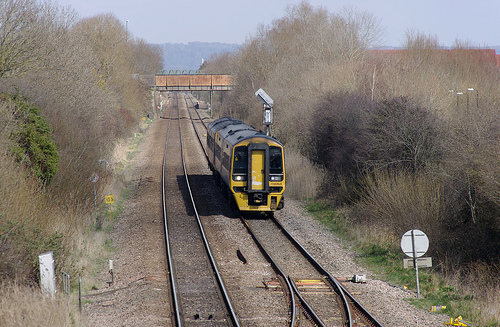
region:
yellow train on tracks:
[202, 112, 285, 220]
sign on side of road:
[100, 190, 124, 207]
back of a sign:
[400, 222, 430, 294]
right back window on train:
[269, 153, 280, 173]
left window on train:
[233, 142, 247, 179]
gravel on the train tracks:
[206, 223, 246, 247]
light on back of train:
[233, 174, 242, 183]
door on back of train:
[252, 145, 262, 191]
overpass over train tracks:
[137, 69, 245, 89]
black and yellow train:
[190, 103, 295, 228]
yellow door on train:
[242, 131, 262, 198]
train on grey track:
[245, 194, 346, 324]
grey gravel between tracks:
[179, 219, 346, 304]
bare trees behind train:
[229, 0, 427, 196]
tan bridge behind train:
[142, 69, 229, 95]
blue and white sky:
[144, 6, 241, 45]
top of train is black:
[205, 107, 265, 156]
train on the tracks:
[191, 102, 291, 218]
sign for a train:
[382, 214, 455, 316]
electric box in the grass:
[29, 240, 73, 322]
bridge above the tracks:
[152, 62, 239, 99]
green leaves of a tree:
[17, 108, 70, 193]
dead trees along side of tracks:
[295, 44, 456, 194]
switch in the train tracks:
[271, 280, 364, 319]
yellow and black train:
[205, 86, 285, 208]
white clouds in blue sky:
[135, 2, 187, 26]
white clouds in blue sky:
[207, 12, 238, 49]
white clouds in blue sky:
[237, 19, 288, 44]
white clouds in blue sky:
[371, 8, 408, 45]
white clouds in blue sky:
[8, 11, 48, 35]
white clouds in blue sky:
[48, 2, 115, 50]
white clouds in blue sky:
[110, 9, 171, 47]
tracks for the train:
[137, 208, 399, 320]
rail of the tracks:
[145, 108, 188, 323]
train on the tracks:
[189, 70, 298, 257]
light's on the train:
[215, 173, 289, 190]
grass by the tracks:
[283, 206, 409, 283]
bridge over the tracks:
[136, 64, 240, 114]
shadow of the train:
[166, 158, 210, 226]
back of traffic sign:
[393, 225, 438, 300]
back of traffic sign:
[397, 217, 440, 305]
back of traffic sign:
[379, 215, 452, 300]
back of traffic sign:
[389, 217, 441, 304]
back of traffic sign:
[384, 217, 446, 299]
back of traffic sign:
[380, 212, 445, 299]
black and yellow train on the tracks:
[204, 116, 286, 214]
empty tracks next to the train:
[161, 89, 241, 326]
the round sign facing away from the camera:
[400, 229, 428, 255]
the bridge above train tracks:
[131, 70, 236, 93]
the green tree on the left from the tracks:
[1, 90, 59, 189]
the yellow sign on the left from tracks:
[102, 193, 115, 223]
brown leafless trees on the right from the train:
[200, 0, 499, 319]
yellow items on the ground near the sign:
[430, 305, 465, 325]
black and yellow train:
[198, 103, 303, 223]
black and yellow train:
[204, 100, 305, 228]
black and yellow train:
[203, 105, 301, 225]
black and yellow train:
[195, 99, 305, 228]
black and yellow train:
[199, 95, 306, 226]